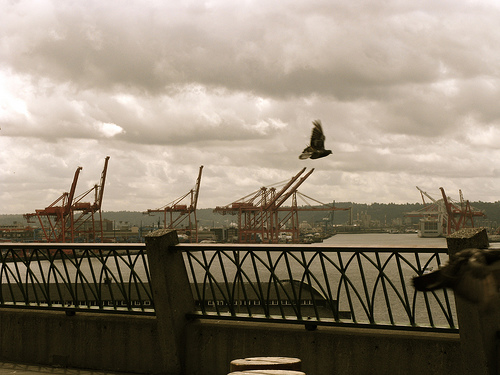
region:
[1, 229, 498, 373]
Bridge arm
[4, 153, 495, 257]
Row of industrial machines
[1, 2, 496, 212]
Cloudy skies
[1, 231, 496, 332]
Body of water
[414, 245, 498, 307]
Face of a black dog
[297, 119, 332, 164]
Bird in the sky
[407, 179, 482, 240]
Industrial machine distant from the bridge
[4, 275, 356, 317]
Dock near the body of water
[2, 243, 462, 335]
Handle bars on the arms of the bridge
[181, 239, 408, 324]
A metal patterned fence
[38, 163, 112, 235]
Orange crane-type construction equipment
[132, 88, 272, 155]
A gray cloudy sky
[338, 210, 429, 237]
A lengthy boat seen from a distance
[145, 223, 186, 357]
A stone fence-post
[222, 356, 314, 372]
The top of a plastic table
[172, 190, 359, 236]
A collection of construction equipment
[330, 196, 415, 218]
A distant horizon of trees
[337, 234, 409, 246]
Gray calm water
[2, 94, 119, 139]
Dark clouds with some brightness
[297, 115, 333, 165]
bird flying in air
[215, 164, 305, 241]
cranes near the water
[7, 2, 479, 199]
dark clouds in sky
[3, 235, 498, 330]
iron railing on bridge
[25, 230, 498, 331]
clam water on bay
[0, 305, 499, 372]
concrete wall of bridge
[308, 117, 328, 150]
wings spread on bird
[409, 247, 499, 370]
dog walking on bridge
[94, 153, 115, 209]
top of crane extended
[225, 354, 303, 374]
round containers on bridge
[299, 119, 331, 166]
bird flying above bridge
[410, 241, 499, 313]
bird flying in front of wall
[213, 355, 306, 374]
two tops of cylinders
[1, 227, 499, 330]
large body of water behind bridge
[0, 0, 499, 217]
sky is covered with grey clouds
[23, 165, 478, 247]
large cranes surround water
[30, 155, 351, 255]
large orange cranes on left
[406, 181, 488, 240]
large orange crane on right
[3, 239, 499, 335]
metal railing on wall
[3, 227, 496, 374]
wall is concrete and metal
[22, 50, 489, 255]
cargo loading/unloading area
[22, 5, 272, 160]
rows of gray clouds in the sky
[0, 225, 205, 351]
railing overlooking a river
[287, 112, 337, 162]
bird soars through the sky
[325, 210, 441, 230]
buildings on the other side of the water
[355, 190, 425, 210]
line of trees at the horizon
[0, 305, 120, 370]
cement base of the railing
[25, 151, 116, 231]
cranes for lifting cargo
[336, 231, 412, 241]
river water